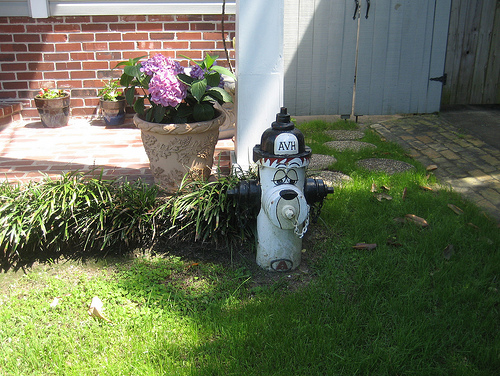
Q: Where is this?
A: This is at the patio.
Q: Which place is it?
A: It is a patio.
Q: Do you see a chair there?
A: No, there are no chairs.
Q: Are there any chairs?
A: No, there are no chairs.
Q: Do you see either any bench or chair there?
A: No, there are no chairs or benches.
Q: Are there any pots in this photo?
A: Yes, there is a pot.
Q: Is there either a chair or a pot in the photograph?
A: Yes, there is a pot.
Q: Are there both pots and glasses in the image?
A: No, there is a pot but no glasses.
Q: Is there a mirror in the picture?
A: No, there are no mirrors.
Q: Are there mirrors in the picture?
A: No, there are no mirrors.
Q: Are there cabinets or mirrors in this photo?
A: No, there are no mirrors or cabinets.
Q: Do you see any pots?
A: Yes, there is a pot.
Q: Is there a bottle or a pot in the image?
A: Yes, there is a pot.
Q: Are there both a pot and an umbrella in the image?
A: No, there is a pot but no umbrellas.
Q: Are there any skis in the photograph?
A: No, there are no skis.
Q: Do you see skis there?
A: No, there are no skis.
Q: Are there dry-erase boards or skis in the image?
A: No, there are no skis or dry-erase boards.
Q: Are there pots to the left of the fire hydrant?
A: Yes, there is a pot to the left of the fire hydrant.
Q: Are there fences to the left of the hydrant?
A: No, there is a pot to the left of the hydrant.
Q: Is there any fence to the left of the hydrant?
A: No, there is a pot to the left of the hydrant.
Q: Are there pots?
A: Yes, there is a pot.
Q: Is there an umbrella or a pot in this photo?
A: Yes, there is a pot.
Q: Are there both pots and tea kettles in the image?
A: No, there is a pot but no tea kettles.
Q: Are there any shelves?
A: No, there are no shelves.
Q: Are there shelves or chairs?
A: No, there are no shelves or chairs.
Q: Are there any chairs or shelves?
A: No, there are no shelves or chairs.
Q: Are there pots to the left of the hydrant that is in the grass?
A: Yes, there is a pot to the left of the hydrant.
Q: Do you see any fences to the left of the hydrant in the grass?
A: No, there is a pot to the left of the fire hydrant.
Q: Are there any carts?
A: No, there are no carts.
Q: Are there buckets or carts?
A: No, there are no carts or buckets.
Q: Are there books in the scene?
A: No, there are no books.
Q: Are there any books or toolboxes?
A: No, there are no books or toolboxes.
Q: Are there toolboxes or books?
A: No, there are no books or toolboxes.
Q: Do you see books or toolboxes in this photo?
A: No, there are no books or toolboxes.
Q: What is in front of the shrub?
A: The plants are in front of the shrub.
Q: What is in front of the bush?
A: The plants are in front of the shrub.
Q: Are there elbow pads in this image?
A: No, there are no elbow pads.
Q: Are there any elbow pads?
A: No, there are no elbow pads.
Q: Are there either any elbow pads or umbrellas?
A: No, there are no elbow pads or umbrellas.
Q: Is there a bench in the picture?
A: No, there are no benches.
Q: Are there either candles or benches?
A: No, there are no benches or candles.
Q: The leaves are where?
A: The leaves are on the ground.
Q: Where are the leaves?
A: The leaves are on the ground.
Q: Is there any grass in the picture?
A: Yes, there is grass.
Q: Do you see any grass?
A: Yes, there is grass.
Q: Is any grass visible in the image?
A: Yes, there is grass.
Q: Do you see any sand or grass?
A: Yes, there is grass.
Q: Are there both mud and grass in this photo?
A: No, there is grass but no mud.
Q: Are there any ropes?
A: No, there are no ropes.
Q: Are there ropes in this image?
A: No, there are no ropes.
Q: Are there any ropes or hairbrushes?
A: No, there are no ropes or hairbrushes.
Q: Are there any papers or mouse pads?
A: No, there are no papers or mouse pads.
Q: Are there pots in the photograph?
A: Yes, there is a pot.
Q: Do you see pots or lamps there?
A: Yes, there is a pot.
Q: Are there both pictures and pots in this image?
A: No, there is a pot but no pictures.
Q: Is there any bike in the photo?
A: No, there are no bikes.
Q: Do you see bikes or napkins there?
A: No, there are no bikes or napkins.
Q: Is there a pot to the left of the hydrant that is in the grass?
A: Yes, there is a pot to the left of the fire hydrant.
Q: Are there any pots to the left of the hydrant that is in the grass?
A: Yes, there is a pot to the left of the fire hydrant.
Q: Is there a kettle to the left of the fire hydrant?
A: No, there is a pot to the left of the fire hydrant.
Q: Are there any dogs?
A: Yes, there is a dog.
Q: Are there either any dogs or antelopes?
A: Yes, there is a dog.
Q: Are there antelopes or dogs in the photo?
A: Yes, there is a dog.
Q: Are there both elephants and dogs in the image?
A: No, there is a dog but no elephants.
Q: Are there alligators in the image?
A: No, there are no alligators.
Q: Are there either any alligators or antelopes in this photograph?
A: No, there are no alligators or antelopes.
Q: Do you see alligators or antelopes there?
A: No, there are no alligators or antelopes.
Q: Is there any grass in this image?
A: Yes, there is grass.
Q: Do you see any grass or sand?
A: Yes, there is grass.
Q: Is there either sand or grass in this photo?
A: Yes, there is grass.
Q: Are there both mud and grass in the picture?
A: No, there is grass but no mud.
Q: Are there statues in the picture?
A: No, there are no statues.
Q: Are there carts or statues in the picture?
A: No, there are no statues or carts.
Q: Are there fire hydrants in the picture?
A: Yes, there is a fire hydrant.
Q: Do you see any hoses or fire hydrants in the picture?
A: Yes, there is a fire hydrant.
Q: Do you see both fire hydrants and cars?
A: No, there is a fire hydrant but no cars.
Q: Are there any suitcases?
A: No, there are no suitcases.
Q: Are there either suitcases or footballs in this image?
A: No, there are no suitcases or footballs.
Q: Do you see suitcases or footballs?
A: No, there are no suitcases or footballs.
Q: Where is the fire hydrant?
A: The fire hydrant is in the grass.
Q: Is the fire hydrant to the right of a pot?
A: Yes, the fire hydrant is to the right of a pot.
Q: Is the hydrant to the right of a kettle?
A: No, the hydrant is to the right of a pot.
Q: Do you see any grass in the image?
A: Yes, there is grass.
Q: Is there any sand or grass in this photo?
A: Yes, there is grass.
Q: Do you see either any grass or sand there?
A: Yes, there is grass.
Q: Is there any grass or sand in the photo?
A: Yes, there is grass.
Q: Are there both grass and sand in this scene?
A: No, there is grass but no sand.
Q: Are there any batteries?
A: No, there are no batteries.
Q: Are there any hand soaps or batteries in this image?
A: No, there are no batteries or hand soaps.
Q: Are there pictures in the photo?
A: No, there are no pictures.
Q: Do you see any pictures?
A: No, there are no pictures.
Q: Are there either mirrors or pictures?
A: No, there are no pictures or mirrors.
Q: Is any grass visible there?
A: Yes, there is grass.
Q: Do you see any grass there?
A: Yes, there is grass.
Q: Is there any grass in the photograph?
A: Yes, there is grass.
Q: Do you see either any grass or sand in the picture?
A: Yes, there is grass.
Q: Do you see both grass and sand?
A: No, there is grass but no sand.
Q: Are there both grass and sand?
A: No, there is grass but no sand.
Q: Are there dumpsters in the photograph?
A: No, there are no dumpsters.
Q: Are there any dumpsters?
A: No, there are no dumpsters.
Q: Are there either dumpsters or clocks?
A: No, there are no dumpsters or clocks.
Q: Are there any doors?
A: Yes, there is a door.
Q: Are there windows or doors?
A: Yes, there is a door.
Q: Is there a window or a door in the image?
A: Yes, there is a door.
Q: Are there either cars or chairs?
A: No, there are no chairs or cars.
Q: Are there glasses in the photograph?
A: No, there are no glasses.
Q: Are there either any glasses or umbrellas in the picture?
A: No, there are no glasses or umbrellas.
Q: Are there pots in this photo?
A: Yes, there is a pot.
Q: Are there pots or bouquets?
A: Yes, there is a pot.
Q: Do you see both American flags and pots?
A: No, there is a pot but no American flags.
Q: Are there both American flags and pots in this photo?
A: No, there is a pot but no American flags.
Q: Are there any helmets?
A: No, there are no helmets.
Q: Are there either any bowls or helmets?
A: No, there are no helmets or bowls.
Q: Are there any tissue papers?
A: No, there are no tissue papers.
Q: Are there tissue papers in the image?
A: No, there are no tissue papers.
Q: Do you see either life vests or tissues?
A: No, there are no tissues or life vests.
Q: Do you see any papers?
A: No, there are no papers.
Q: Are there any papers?
A: No, there are no papers.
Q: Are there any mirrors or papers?
A: No, there are no papers or mirrors.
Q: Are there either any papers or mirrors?
A: No, there are no papers or mirrors.